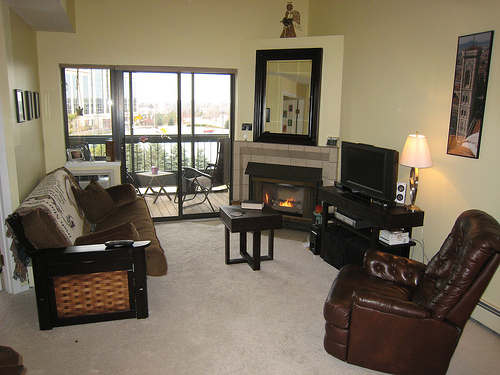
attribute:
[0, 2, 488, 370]
room — white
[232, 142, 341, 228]
fireplace — lit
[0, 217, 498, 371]
carpet — white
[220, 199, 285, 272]
table — small, brown, dark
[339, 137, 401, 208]
tv — flat panel, here, black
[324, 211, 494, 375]
chair — brown, leather, recliner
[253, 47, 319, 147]
mirror — black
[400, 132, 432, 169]
lampshade — here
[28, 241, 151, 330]
end table — brown, tan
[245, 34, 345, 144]
wall — here, white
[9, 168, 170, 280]
sofa — brown, here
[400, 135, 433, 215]
lamp — bright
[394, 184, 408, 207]
speakers — silver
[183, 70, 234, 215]
door pane — here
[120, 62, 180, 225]
door pane — here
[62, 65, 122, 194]
door pane — here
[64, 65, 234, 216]
door — glassed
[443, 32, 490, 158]
picture frame — here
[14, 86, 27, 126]
picture frame — here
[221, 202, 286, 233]
table top — black